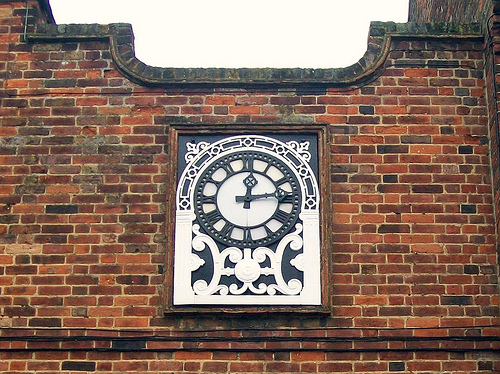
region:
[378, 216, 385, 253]
part of a brick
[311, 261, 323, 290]
part of a clock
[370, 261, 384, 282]
side of a wall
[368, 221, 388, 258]
part of a brick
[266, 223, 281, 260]
edge of a clock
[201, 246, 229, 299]
side of a clock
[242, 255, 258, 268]
part of a clock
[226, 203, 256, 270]
edge of a clock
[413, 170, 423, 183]
part of a brick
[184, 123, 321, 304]
white clock on wall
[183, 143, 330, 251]
clock uses roman numerals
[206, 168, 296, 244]
roman numerals are black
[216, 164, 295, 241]
clock has black hands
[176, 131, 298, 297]
arched frame around clock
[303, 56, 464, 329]
red and brown brick wall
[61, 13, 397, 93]
dark bricks on top of wall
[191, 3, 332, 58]
sky is bright and grey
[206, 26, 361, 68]
sky has thick clouds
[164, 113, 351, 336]
clock inset in wall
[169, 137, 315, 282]
this is a clock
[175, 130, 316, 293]
the clock is white in color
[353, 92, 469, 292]
this is the wall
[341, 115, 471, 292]
the wall is made of bricks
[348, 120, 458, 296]
the wall is red in color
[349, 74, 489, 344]
the wall is high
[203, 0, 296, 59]
this is the sky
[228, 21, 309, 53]
the sky is white in color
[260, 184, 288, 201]
this is the minute hand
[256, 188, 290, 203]
the hand is long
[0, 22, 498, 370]
A clock mounted on a brick wall.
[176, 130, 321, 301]
Background of the clock is blue.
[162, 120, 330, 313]
Clock in a brown wooden frame.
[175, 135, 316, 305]
A white decorative design around the clock.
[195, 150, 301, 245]
Clock has a round face and blue numbers.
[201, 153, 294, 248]
Roman numerals on a clock.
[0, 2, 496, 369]
The wall is brick.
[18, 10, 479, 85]
Downward arch at the top of the wall.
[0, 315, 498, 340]
A ledge on the wall below the clock.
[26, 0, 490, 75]
A gray sky above the wall.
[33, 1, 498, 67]
roof of a building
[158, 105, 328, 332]
framed clock on a wall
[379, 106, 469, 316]
brick facade of a wall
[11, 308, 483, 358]
ledge on a wall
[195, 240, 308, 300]
decorative scroll on a clock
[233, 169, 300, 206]
black hands of a clock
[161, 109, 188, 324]
wooden frame surrounding clock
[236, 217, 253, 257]
black roman numeral six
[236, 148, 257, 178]
black roman numeral twelve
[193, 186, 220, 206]
black roman numeral nine